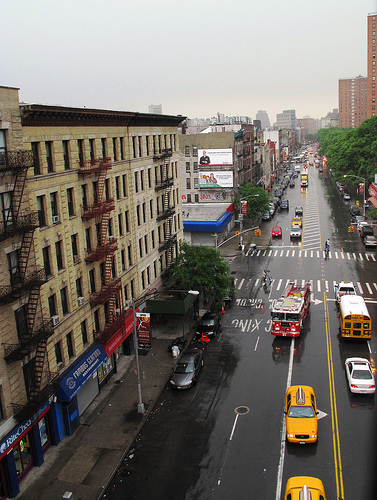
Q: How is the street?
A: Wet.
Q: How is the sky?
A: Cloudy.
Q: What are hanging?
A: Traffic lights.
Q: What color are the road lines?
A: Yellow and white.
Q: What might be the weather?
A: Rainy.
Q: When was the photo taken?
A: Daytime.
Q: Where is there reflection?
A: On the wet street.